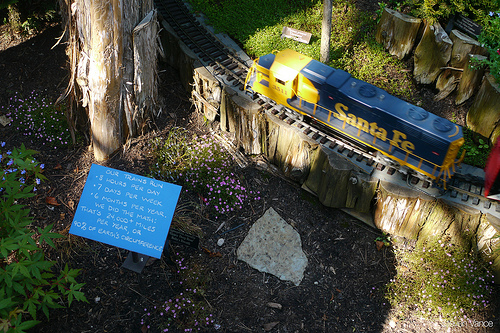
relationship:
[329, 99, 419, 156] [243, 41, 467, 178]
letter on train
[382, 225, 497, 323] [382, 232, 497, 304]
patch of flowers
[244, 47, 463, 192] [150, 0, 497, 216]
train on track